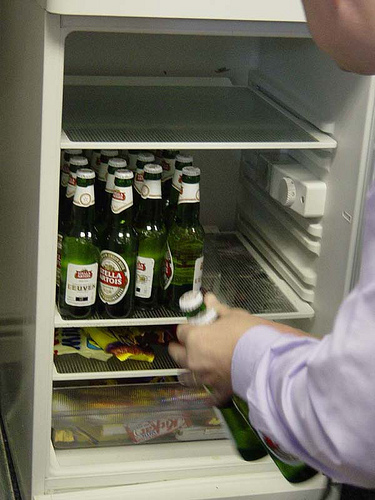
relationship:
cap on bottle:
[177, 161, 204, 181] [172, 165, 213, 315]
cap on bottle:
[142, 163, 163, 175] [136, 162, 168, 314]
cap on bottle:
[113, 168, 134, 181] [95, 168, 141, 318]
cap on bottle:
[73, 166, 98, 181] [56, 165, 105, 318]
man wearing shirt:
[166, 0, 373, 498] [220, 161, 374, 488]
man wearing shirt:
[166, 0, 373, 498] [217, 304, 368, 410]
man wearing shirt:
[166, 0, 373, 498] [229, 176, 373, 491]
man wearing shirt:
[166, 0, 373, 498] [255, 281, 373, 448]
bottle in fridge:
[157, 163, 204, 313] [0, 1, 375, 500]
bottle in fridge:
[129, 160, 169, 309] [0, 1, 375, 500]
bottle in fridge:
[94, 164, 136, 314] [0, 1, 375, 500]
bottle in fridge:
[59, 164, 104, 324] [0, 1, 375, 500]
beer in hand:
[188, 306, 266, 485] [164, 291, 260, 415]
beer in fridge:
[56, 147, 206, 317] [0, 1, 375, 500]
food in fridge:
[53, 324, 165, 363] [0, 1, 375, 500]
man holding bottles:
[166, 0, 373, 498] [163, 282, 242, 385]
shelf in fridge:
[58, 72, 345, 152] [0, 1, 372, 497]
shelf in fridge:
[52, 226, 317, 331] [0, 1, 372, 497]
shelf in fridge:
[51, 332, 188, 385] [0, 1, 372, 497]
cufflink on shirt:
[199, 285, 309, 416] [204, 240, 368, 439]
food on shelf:
[60, 332, 166, 365] [50, 339, 187, 388]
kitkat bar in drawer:
[126, 413, 184, 441] [51, 383, 234, 443]